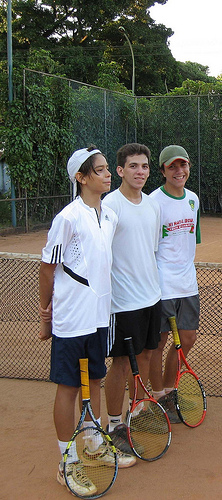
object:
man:
[147, 144, 202, 427]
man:
[101, 140, 161, 458]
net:
[0, 247, 220, 401]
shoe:
[55, 460, 97, 496]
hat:
[158, 144, 189, 167]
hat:
[67, 144, 103, 203]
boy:
[40, 144, 137, 499]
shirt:
[40, 194, 119, 339]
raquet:
[167, 314, 207, 430]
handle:
[166, 314, 181, 354]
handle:
[123, 336, 139, 380]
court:
[0, 267, 221, 499]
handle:
[78, 358, 92, 402]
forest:
[0, 1, 222, 228]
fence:
[0, 58, 221, 224]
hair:
[116, 143, 151, 170]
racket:
[123, 334, 171, 465]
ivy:
[2, 98, 35, 223]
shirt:
[148, 187, 201, 302]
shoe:
[81, 441, 137, 467]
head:
[159, 145, 189, 190]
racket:
[63, 355, 118, 495]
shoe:
[105, 424, 142, 456]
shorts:
[159, 294, 199, 333]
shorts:
[49, 328, 106, 388]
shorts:
[106, 299, 161, 359]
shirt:
[101, 188, 161, 315]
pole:
[5, 2, 18, 232]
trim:
[162, 155, 189, 166]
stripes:
[58, 243, 62, 264]